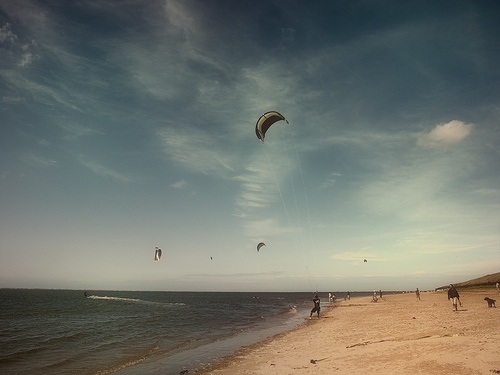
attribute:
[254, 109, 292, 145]
parasail — large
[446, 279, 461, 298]
jacket. — dark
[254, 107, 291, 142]
kite — huge, blue and white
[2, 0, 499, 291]
sky — blue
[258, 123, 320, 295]
string — white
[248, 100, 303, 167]
parasail — large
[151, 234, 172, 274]
parasail — large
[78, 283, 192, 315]
trail — white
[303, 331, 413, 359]
sand — brown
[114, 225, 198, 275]
sky — blue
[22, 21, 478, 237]
clouds — thin, white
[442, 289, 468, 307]
capris — khaki